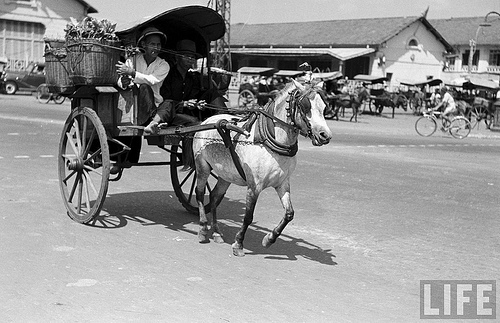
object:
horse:
[190, 77, 333, 256]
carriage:
[56, 0, 229, 224]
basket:
[35, 24, 126, 86]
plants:
[64, 17, 123, 42]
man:
[113, 21, 178, 137]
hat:
[141, 23, 169, 43]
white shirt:
[123, 51, 172, 106]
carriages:
[0, 1, 500, 130]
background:
[14, 5, 495, 145]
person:
[414, 82, 474, 141]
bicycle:
[413, 107, 474, 139]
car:
[4, 53, 46, 94]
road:
[7, 94, 497, 321]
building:
[0, 0, 101, 78]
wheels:
[57, 107, 227, 223]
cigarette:
[148, 51, 156, 59]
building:
[208, 21, 451, 89]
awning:
[213, 46, 369, 68]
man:
[167, 43, 229, 115]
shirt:
[168, 68, 209, 98]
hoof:
[260, 229, 279, 248]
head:
[284, 77, 334, 147]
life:
[424, 283, 495, 315]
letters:
[419, 279, 497, 319]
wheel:
[166, 114, 235, 214]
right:
[165, 21, 338, 226]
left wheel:
[59, 106, 110, 223]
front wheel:
[415, 114, 438, 137]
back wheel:
[449, 115, 472, 139]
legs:
[196, 166, 295, 258]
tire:
[8, 81, 19, 93]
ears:
[290, 72, 332, 97]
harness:
[175, 92, 299, 151]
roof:
[111, 5, 232, 36]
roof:
[226, 16, 447, 58]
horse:
[329, 89, 372, 121]